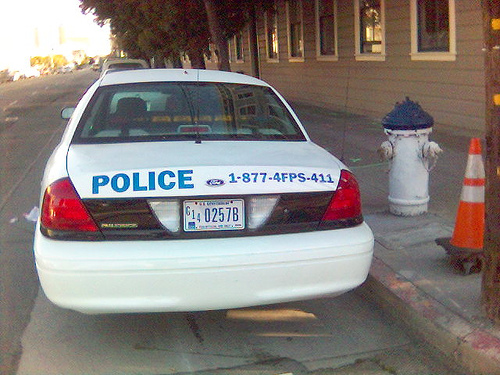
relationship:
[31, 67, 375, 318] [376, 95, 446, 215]
car parked near fire hydrant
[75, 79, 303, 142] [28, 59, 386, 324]
window on car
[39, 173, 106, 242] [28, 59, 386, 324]
light on car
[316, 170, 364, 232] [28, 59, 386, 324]
light on car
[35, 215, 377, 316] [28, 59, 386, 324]
bumper on car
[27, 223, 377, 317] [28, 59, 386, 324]
bumper on car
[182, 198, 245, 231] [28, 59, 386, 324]
plate on car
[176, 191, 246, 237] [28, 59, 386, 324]
plate on car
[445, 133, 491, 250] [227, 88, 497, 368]
cone on sidewalk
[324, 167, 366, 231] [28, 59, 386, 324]
light on car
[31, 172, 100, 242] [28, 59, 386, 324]
light on car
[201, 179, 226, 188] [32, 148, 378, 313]
logo on back of car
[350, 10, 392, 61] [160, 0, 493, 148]
window on side of building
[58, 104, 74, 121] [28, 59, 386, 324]
mirror on car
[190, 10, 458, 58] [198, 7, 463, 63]
row of windows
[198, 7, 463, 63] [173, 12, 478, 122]
windows on building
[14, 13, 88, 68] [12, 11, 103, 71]
light in sky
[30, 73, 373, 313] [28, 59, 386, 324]
back of parked car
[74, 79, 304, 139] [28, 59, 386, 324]
window of car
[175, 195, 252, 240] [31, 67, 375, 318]
license plate on car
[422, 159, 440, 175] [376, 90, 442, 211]
chain hanging from hydrant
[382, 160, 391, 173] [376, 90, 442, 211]
chain hanging from hydrant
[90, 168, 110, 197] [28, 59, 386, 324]
letter on car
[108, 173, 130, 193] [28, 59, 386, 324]
letter on car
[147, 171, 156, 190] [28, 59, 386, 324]
letter on car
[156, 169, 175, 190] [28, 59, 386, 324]
letter on car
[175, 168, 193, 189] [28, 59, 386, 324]
letter on car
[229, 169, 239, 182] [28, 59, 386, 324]
number 1 on car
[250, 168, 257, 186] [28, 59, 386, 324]
number 7 on car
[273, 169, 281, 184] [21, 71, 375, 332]
number 4 on car